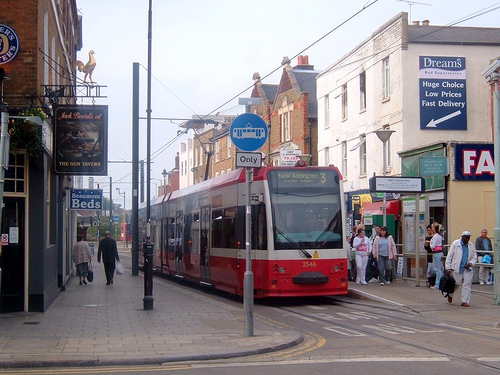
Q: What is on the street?
A: Trolley train.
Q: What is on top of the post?
A: The sign.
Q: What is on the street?
A: Yellow lines.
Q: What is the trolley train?
A: White and red.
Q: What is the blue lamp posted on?
A: Street.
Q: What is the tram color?
A: Red and white.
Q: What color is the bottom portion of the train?
A: Red.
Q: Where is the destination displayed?
A: On the top of the bus.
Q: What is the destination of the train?
A: New Addington.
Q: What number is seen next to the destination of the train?
A: 3.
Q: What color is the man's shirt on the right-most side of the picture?
A: Blue.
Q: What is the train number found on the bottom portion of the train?
A: 2546.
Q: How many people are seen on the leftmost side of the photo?
A: Two.